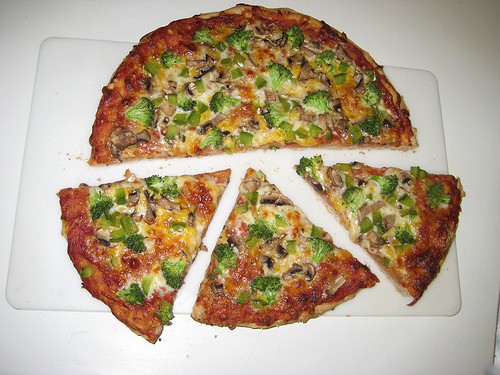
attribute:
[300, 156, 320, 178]
broccoli — small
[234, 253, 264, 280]
pizza sauce — red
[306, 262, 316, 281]
mushroom — thinly sliced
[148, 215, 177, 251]
cheese — yellow orange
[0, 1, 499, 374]
table — white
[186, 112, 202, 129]
bell pepper — green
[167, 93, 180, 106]
bell pepper — green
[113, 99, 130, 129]
sauce — red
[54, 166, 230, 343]
pizza — uneven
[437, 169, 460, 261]
crust — WELL DONE 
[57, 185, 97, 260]
crunchy pizza — of pizza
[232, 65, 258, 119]
cheese bubbles — caramelized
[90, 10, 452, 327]
pizza — cut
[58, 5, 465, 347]
pizza — VEGGIE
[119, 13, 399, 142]
pizza — delicious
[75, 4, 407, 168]
pizza — uneven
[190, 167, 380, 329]
pizza — triangular, uneven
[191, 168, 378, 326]
crust — thin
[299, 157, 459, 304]
pizza — triangular, uneven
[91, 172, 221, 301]
cheese — WELL DONE 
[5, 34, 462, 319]
cutting board — white, clear, small